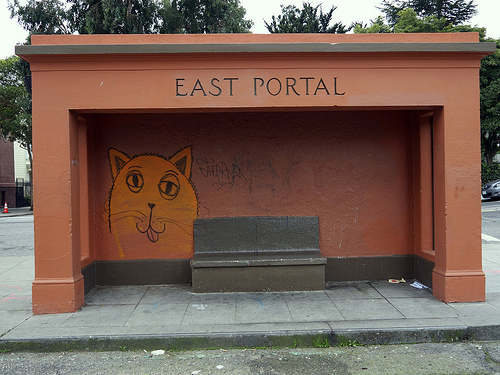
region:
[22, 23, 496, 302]
shelter over the bench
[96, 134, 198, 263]
cat painted onto the shelter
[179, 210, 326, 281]
cement bench underneath the shelter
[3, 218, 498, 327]
sidewalk bench and shelter are on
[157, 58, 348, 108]
east portal written on front of shelter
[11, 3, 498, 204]
trees behind the shelter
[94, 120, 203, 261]
orange cat with black eyes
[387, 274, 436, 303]
trash under the shelter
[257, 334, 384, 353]
weeds growing along sidewalk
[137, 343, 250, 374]
trash in the street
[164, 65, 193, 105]
a letter on the shade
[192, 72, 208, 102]
a letter on the shade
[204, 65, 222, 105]
a letter on the shade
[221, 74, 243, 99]
a letter on the shade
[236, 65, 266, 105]
a letter on the shade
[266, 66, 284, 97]
a letter on the shade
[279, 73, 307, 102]
a letter on the shade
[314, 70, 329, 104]
a letter on the shade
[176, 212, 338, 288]
a bench in the shade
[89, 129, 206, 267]
a drawing on the shade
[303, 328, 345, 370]
edge of a road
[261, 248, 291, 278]
edge of a bench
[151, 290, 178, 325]
ppart of a floor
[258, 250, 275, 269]
part of a bench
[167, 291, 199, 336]
part of a floor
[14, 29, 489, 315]
peach colored bus stop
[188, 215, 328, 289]
concrest bench at a bus stop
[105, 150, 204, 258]
orange cat painted on wall of a bus stop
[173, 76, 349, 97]
location of bus stop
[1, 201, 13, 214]
orange traffic cone in background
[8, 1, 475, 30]
trees showing above a bus stop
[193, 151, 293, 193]
graffiti in back wall at a bus stop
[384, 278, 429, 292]
litter on the floor at a bus stop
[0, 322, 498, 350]
concrete curb in front of bus stop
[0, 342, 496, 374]
road in front of bus stop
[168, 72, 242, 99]
The word East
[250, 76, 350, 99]
The word Portal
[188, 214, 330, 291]
Bench made of cement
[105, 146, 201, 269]
A drawing of a cat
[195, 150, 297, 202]
graffiti on the wall of the east portal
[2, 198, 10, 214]
an orange traffic cone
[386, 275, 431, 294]
trash on the ground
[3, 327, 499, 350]
a street curb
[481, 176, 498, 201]
the nose of a silver car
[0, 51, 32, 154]
A tree behind the east portal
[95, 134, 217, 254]
cat drawn on wall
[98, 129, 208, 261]
cat drawn on wall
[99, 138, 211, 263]
cat drawn on wall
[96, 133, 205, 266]
cat drawn on wall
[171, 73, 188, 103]
A letter on a building.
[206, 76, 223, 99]
A letter on a building.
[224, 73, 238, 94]
A letter on a building.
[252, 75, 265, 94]
A letter on a building.